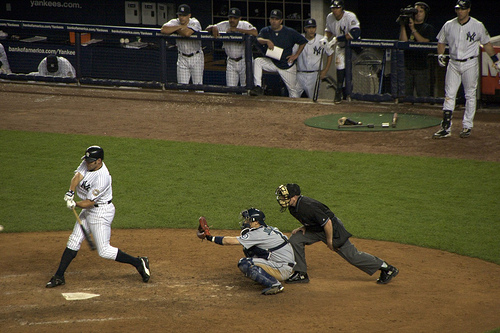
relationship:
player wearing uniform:
[37, 45, 67, 76] [40, 67, 73, 79]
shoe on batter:
[128, 251, 156, 282] [38, 126, 164, 291]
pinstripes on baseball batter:
[65, 207, 118, 259] [44, 145, 153, 283]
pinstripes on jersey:
[65, 207, 118, 259] [61, 172, 135, 209]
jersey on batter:
[61, 172, 135, 209] [40, 133, 152, 288]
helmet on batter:
[78, 143, 117, 172] [52, 185, 124, 267]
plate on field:
[57, 291, 101, 301] [0, 75, 498, 330]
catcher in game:
[195, 206, 297, 297] [44, 125, 401, 311]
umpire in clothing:
[273, 181, 400, 287] [297, 209, 367, 257]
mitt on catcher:
[196, 216, 213, 243] [186, 203, 302, 286]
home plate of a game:
[61, 291, 101, 301] [44, 125, 401, 311]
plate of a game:
[57, 291, 101, 301] [18, 119, 414, 307]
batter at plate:
[42, 143, 150, 291] [42, 282, 113, 316]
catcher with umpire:
[195, 206, 297, 297] [273, 181, 400, 287]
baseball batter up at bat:
[44, 144, 153, 289] [69, 206, 99, 255]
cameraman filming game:
[395, 0, 444, 97] [37, 119, 452, 329]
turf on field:
[140, 151, 355, 236] [125, 95, 273, 200]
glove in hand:
[187, 201, 222, 248] [195, 222, 209, 253]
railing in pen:
[74, 25, 180, 89] [55, 5, 424, 93]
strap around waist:
[257, 227, 299, 267] [253, 234, 293, 264]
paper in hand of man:
[264, 44, 289, 66] [239, 9, 306, 103]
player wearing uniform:
[184, 204, 316, 301] [227, 225, 325, 285]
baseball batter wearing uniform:
[44, 144, 153, 289] [292, 202, 387, 274]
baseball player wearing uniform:
[266, 180, 403, 284] [292, 202, 387, 274]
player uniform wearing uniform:
[431, 0, 497, 141] [435, 17, 492, 127]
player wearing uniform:
[290, 14, 333, 104] [298, 36, 333, 101]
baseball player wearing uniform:
[204, 7, 259, 93] [208, 20, 254, 85]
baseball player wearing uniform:
[155, 7, 203, 83] [160, 17, 206, 85]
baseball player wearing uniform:
[204, 7, 259, 93] [218, 23, 246, 70]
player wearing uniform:
[327, 3, 357, 103] [320, 11, 358, 95]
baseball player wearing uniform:
[212, 7, 266, 88] [213, 20, 256, 82]